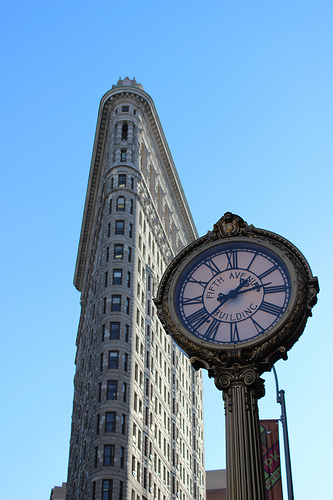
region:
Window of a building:
[97, 443, 114, 470]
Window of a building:
[102, 405, 116, 433]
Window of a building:
[103, 376, 123, 406]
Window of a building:
[106, 344, 126, 372]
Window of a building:
[106, 313, 126, 348]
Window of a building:
[111, 292, 125, 314]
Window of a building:
[113, 259, 125, 288]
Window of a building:
[112, 217, 127, 236]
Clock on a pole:
[171, 209, 310, 377]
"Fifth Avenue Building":
[129, 190, 320, 406]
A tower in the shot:
[30, 56, 296, 498]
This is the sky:
[6, 298, 49, 456]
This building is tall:
[49, 66, 258, 498]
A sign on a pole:
[252, 405, 308, 494]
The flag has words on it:
[244, 405, 295, 498]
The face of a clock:
[167, 235, 298, 362]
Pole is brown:
[190, 362, 285, 499]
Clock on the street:
[124, 184, 331, 438]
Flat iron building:
[34, 39, 225, 481]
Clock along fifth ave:
[131, 198, 326, 401]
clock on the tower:
[158, 233, 314, 353]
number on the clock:
[218, 320, 245, 350]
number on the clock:
[243, 311, 262, 335]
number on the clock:
[208, 318, 221, 341]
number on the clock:
[257, 297, 283, 317]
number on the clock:
[249, 299, 277, 318]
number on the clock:
[211, 323, 219, 340]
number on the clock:
[221, 250, 238, 269]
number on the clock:
[241, 248, 262, 275]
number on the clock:
[260, 260, 281, 282]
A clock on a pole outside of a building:
[158, 209, 324, 373]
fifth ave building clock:
[160, 225, 302, 373]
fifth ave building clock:
[149, 219, 305, 369]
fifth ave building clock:
[158, 220, 302, 359]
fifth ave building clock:
[154, 217, 306, 360]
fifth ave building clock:
[151, 213, 302, 364]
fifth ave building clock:
[151, 215, 313, 368]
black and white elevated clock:
[170, 234, 293, 348]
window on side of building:
[102, 408, 119, 437]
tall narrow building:
[58, 71, 211, 498]